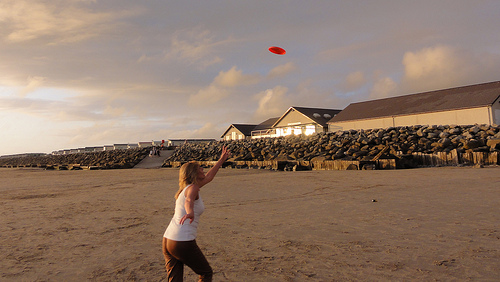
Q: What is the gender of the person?
A: Female.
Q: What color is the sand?
A: Tan.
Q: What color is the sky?
A: Blue.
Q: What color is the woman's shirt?
A: White.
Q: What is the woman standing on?
A: Sand.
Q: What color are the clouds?
A: White.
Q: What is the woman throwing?
A: Frisbee.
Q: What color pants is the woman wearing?
A: Black.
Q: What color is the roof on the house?
A: Brown.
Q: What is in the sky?
A: Clouds.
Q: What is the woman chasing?
A: A frisbee.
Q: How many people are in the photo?
A: One.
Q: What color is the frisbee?
A: Red.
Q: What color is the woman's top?
A: White.